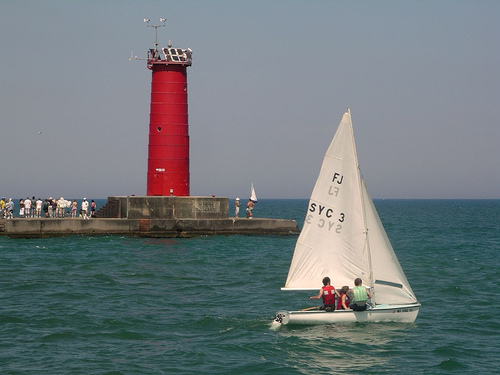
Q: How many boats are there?
A: Two.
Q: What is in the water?
A: Sailboat.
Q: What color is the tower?
A: Red.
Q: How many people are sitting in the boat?
A: Three.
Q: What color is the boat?
A: White.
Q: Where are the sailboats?
A: Ocean.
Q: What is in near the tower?
A: Dock.